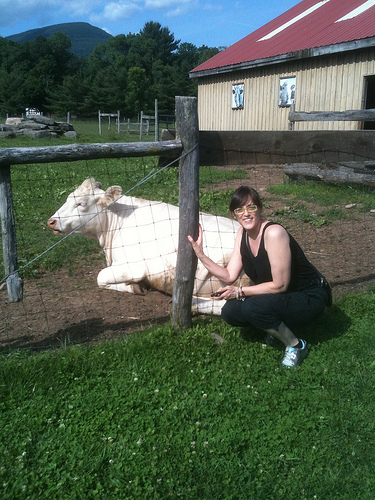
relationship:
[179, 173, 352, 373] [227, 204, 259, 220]
woman wearing glasses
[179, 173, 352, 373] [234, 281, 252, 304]
woman wearing bracelets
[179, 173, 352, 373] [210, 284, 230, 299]
woman holds cellphone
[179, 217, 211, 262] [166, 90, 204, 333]
hand on post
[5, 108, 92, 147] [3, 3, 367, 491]
rocks are on farm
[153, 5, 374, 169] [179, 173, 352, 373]
barn behind woman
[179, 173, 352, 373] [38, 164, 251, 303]
woman in front of cow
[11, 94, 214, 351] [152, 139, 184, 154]
fence made of wood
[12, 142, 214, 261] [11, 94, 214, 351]
grass behind fence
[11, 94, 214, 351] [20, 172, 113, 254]
fence made of wire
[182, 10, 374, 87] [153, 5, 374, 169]
roof on barn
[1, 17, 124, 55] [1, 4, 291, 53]
mountain in front of sky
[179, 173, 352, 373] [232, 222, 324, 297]
woman in tank top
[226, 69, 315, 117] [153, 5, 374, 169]
two windows on barn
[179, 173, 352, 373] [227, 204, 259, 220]
woman wore glasses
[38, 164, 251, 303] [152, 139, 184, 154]
cow behind wood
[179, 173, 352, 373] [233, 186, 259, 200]
woman has dark hair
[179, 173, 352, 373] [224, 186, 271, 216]
woman has dark hair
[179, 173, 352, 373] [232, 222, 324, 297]
woman wearing tank top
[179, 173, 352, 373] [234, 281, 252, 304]
woman wears bracelets